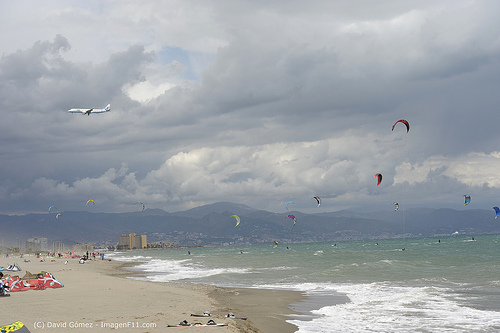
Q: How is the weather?
A: It is cloudy.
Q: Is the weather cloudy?
A: Yes, it is cloudy.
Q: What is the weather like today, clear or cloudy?
A: It is cloudy.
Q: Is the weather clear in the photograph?
A: No, it is cloudy.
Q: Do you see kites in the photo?
A: Yes, there is a kite.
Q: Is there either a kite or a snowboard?
A: Yes, there is a kite.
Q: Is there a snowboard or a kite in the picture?
A: Yes, there is a kite.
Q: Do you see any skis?
A: No, there are no skis.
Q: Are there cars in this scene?
A: No, there are no cars.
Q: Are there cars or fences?
A: No, there are no cars or fences.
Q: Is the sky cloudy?
A: Yes, the sky is cloudy.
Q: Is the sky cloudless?
A: No, the sky is cloudy.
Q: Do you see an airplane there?
A: Yes, there is an airplane.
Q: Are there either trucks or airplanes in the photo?
A: Yes, there is an airplane.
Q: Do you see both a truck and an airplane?
A: No, there is an airplane but no trucks.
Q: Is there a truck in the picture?
A: No, there are no trucks.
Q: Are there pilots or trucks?
A: No, there are no trucks or pilots.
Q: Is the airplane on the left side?
A: Yes, the airplane is on the left of the image.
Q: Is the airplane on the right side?
A: No, the airplane is on the left of the image.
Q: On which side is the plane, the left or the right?
A: The plane is on the left of the image.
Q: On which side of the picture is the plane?
A: The plane is on the left of the image.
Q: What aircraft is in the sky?
A: The aircraft is an airplane.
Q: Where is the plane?
A: The plane is in the sky.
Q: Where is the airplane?
A: The plane is in the sky.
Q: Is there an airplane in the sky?
A: Yes, there is an airplane in the sky.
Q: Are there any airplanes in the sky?
A: Yes, there is an airplane in the sky.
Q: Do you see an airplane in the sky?
A: Yes, there is an airplane in the sky.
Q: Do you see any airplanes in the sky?
A: Yes, there is an airplane in the sky.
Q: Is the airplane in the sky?
A: Yes, the airplane is in the sky.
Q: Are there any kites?
A: Yes, there is a kite.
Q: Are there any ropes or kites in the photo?
A: Yes, there is a kite.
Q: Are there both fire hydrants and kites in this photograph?
A: No, there is a kite but no fire hydrants.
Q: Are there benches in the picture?
A: No, there are no benches.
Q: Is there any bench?
A: No, there are no benches.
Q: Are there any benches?
A: No, there are no benches.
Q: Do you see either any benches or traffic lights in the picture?
A: No, there are no benches or traffic lights.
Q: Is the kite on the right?
A: Yes, the kite is on the right of the image.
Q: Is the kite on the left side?
A: No, the kite is on the right of the image.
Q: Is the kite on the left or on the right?
A: The kite is on the right of the image.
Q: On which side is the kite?
A: The kite is on the right of the image.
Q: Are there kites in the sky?
A: Yes, there is a kite in the sky.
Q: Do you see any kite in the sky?
A: Yes, there is a kite in the sky.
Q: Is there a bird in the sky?
A: No, there is a kite in the sky.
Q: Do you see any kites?
A: Yes, there is a kite.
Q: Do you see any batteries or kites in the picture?
A: Yes, there is a kite.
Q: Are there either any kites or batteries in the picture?
A: Yes, there is a kite.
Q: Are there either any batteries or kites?
A: Yes, there is a kite.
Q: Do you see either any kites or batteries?
A: Yes, there is a kite.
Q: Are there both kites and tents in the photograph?
A: No, there is a kite but no tents.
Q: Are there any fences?
A: No, there are no fences.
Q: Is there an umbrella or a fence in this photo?
A: No, there are no fences or umbrellas.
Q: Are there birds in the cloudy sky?
A: No, there is a kite in the sky.